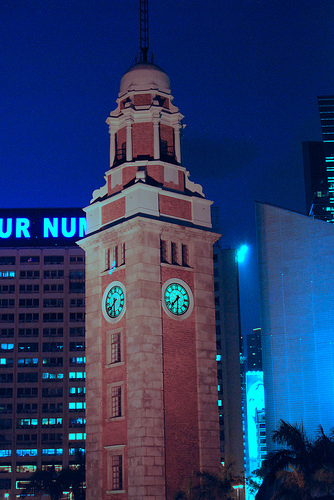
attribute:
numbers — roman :
[179, 288, 186, 315]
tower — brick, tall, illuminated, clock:
[75, 27, 222, 498]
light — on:
[1, 269, 16, 277]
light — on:
[0, 342, 11, 349]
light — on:
[19, 419, 64, 423]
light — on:
[42, 371, 64, 381]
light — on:
[66, 431, 86, 441]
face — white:
[164, 281, 188, 313]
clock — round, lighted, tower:
[153, 264, 195, 319]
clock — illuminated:
[169, 290, 190, 309]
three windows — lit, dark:
[158, 238, 199, 267]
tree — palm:
[256, 413, 333, 491]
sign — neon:
[6, 205, 90, 232]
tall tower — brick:
[84, 64, 242, 496]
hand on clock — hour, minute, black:
[164, 293, 184, 310]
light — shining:
[232, 239, 263, 281]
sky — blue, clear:
[4, 8, 316, 216]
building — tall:
[81, 64, 215, 468]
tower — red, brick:
[71, 58, 242, 461]